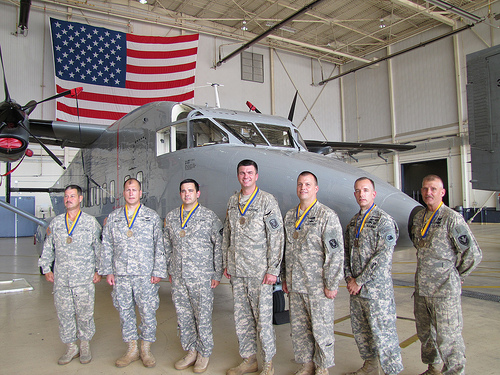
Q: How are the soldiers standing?
A: In a row.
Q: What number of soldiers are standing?
A: Seven.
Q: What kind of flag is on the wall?
A: American flag.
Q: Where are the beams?
A: On the ceiling.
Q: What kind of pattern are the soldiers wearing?
A: Camouflage.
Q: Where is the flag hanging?
A: On the wall.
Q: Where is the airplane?
A: Behind the soldiers.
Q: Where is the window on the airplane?
A: In the front.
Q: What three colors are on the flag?
A: Red, white and blue.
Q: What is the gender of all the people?
A: Male.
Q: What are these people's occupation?
A: Service Men.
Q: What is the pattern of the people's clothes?
A: Camouflage.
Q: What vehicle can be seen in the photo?
A: Airplane.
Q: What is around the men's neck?
A: Medals.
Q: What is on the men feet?
A: Brown boots.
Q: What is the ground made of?
A: Concrete.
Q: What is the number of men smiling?
A: Three.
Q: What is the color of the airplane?
A: Gray.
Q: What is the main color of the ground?
A: Brown.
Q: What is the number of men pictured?
A: 7.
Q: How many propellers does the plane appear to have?
A: Two.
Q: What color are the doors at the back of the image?
A: Blue.